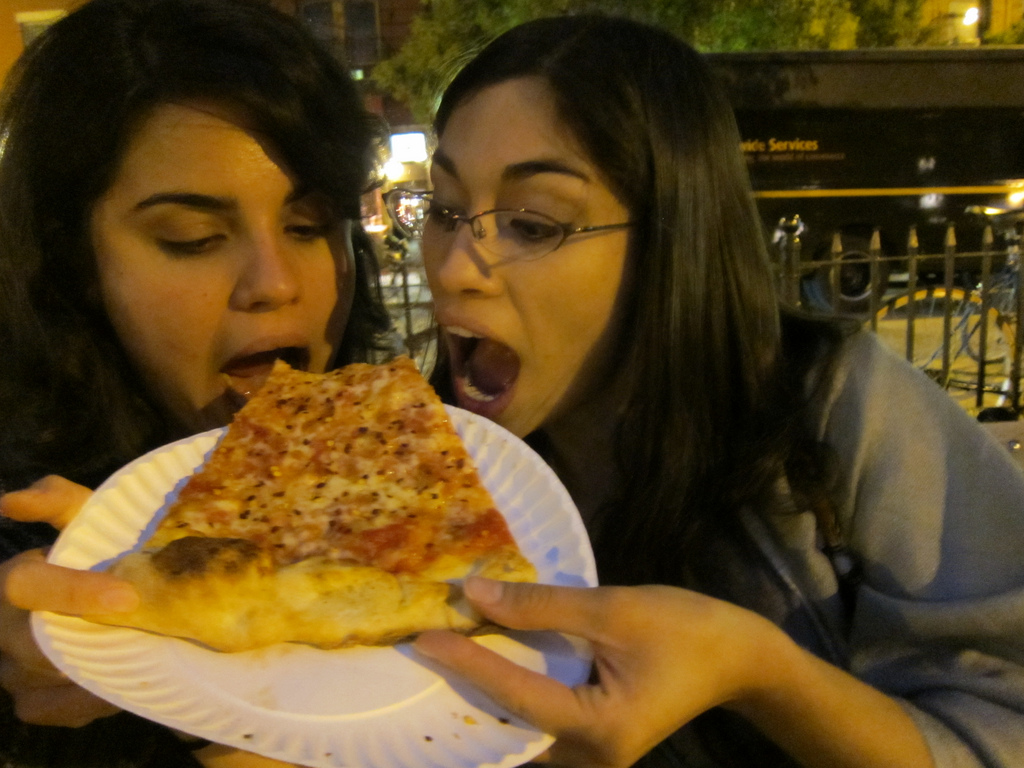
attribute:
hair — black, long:
[439, 19, 792, 549]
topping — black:
[149, 521, 305, 576]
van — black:
[686, 39, 993, 284]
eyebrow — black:
[127, 186, 249, 219]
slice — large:
[73, 338, 585, 660]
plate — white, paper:
[31, 398, 611, 764]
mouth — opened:
[426, 309, 524, 420]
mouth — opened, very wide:
[430, 316, 523, 420]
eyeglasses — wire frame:
[377, 188, 628, 260]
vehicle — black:
[687, 50, 1022, 312]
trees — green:
[368, 3, 1017, 122]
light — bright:
[381, 130, 429, 178]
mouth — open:
[430, 310, 521, 416]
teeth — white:
[441, 325, 485, 343]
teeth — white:
[452, 376, 504, 409]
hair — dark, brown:
[430, 18, 845, 597]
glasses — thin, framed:
[376, 186, 631, 256]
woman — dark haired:
[9, 4, 411, 763]